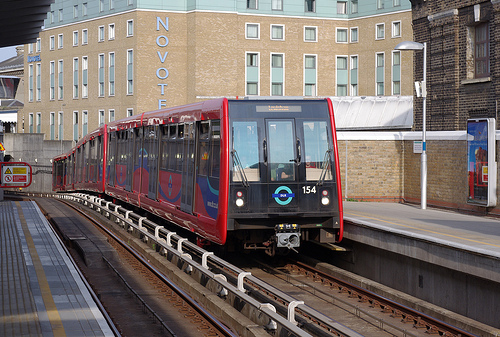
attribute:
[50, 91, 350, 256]
train — blue, long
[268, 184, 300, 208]
emblem — blue, turqoise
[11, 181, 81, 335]
platform — yellow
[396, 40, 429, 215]
pole — silver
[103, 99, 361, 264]
train — driving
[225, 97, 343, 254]
front — circle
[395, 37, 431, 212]
light post — shiny, silver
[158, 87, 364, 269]
train — red, black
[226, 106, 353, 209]
window — brown